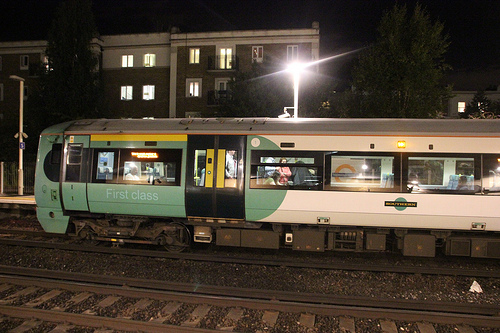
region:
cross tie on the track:
[256, 302, 277, 327]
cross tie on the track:
[293, 312, 316, 330]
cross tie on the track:
[336, 315, 356, 330]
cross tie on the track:
[188, 300, 215, 318]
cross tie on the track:
[150, 298, 179, 327]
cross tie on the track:
[118, 298, 153, 320]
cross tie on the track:
[84, 294, 121, 312]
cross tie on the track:
[373, 317, 398, 332]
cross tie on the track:
[413, 320, 435, 330]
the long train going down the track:
[33, 113, 495, 252]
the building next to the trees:
[96, 25, 323, 116]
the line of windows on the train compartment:
[60, 140, 498, 197]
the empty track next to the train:
[1, 260, 496, 332]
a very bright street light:
[282, 59, 312, 83]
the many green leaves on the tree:
[353, 7, 458, 127]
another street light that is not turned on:
[8, 67, 30, 196]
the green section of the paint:
[36, 133, 290, 240]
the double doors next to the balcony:
[211, 43, 233, 70]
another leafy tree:
[43, 20, 103, 119]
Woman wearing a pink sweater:
[276, 165, 291, 181]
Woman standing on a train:
[273, 154, 293, 186]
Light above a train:
[288, 57, 305, 118]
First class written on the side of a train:
[105, 186, 162, 202]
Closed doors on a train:
[186, 128, 246, 220]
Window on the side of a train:
[406, 153, 478, 190]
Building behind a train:
[1, 25, 331, 115]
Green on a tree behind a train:
[332, 0, 455, 115]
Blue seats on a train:
[439, 172, 474, 189]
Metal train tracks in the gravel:
[2, 261, 499, 331]